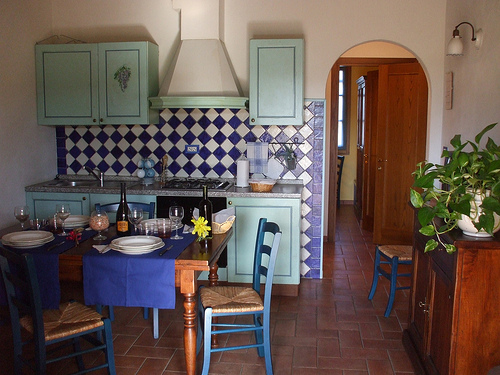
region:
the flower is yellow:
[192, 217, 211, 239]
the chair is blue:
[261, 227, 274, 279]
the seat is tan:
[217, 287, 240, 306]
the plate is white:
[126, 235, 145, 250]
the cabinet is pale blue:
[264, 63, 284, 103]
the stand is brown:
[438, 269, 478, 317]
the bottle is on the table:
[114, 207, 131, 239]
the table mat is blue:
[111, 266, 148, 290]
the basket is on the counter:
[250, 179, 278, 192]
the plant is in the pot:
[448, 159, 498, 211]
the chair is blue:
[204, 222, 294, 366]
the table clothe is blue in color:
[91, 257, 172, 305]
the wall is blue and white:
[181, 120, 239, 172]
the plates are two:
[106, 225, 163, 260]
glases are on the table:
[131, 201, 193, 233]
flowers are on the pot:
[418, 131, 499, 208]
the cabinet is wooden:
[392, 233, 490, 372]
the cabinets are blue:
[46, 45, 153, 135]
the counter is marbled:
[278, 178, 299, 198]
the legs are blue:
[366, 256, 406, 311]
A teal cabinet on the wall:
[244, 34, 309, 131]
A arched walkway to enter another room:
[321, 35, 436, 273]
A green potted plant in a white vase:
[403, 119, 498, 258]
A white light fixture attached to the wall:
[443, 16, 486, 64]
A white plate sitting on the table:
[105, 230, 166, 256]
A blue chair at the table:
[197, 215, 284, 374]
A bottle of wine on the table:
[108, 178, 135, 243]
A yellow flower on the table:
[185, 211, 216, 251]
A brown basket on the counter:
[238, 174, 280, 196]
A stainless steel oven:
[153, 170, 235, 197]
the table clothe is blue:
[82, 255, 184, 297]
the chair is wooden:
[201, 237, 283, 360]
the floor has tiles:
[321, 298, 369, 362]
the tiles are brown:
[311, 300, 366, 364]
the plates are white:
[104, 230, 159, 252]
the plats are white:
[10, 231, 52, 246]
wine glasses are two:
[127, 207, 184, 230]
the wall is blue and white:
[88, 129, 220, 148]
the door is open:
[327, 69, 442, 237]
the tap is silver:
[77, 165, 112, 190]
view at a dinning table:
[29, 170, 288, 322]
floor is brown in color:
[286, 305, 381, 359]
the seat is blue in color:
[207, 290, 277, 352]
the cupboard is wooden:
[427, 257, 484, 360]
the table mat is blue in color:
[103, 253, 169, 294]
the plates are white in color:
[116, 231, 155, 256]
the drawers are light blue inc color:
[57, 43, 129, 108]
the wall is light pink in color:
[312, 0, 368, 55]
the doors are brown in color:
[382, 65, 417, 192]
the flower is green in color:
[447, 140, 494, 185]